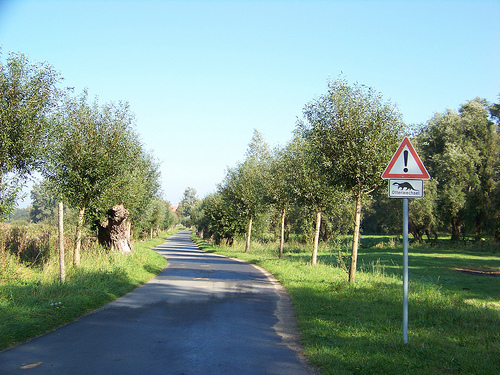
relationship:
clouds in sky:
[173, 72, 219, 123] [18, 7, 498, 108]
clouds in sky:
[163, 141, 234, 177] [3, 1, 495, 49]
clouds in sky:
[119, 57, 277, 180] [0, 2, 498, 208]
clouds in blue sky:
[135, 70, 255, 191] [164, 32, 240, 98]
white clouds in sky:
[116, 50, 184, 100] [0, 0, 500, 203]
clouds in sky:
[104, 39, 251, 179] [0, 2, 498, 208]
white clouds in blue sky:
[172, 140, 225, 182] [128, 15, 478, 63]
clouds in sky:
[110, 53, 257, 178] [13, 6, 496, 79]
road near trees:
[145, 207, 269, 365] [207, 106, 386, 266]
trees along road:
[203, 169, 368, 288] [38, 222, 311, 367]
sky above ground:
[126, 37, 290, 155] [22, 210, 467, 373]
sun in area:
[42, 13, 322, 149] [7, 185, 497, 372]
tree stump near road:
[93, 204, 132, 256] [0, 228, 319, 373]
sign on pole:
[366, 134, 463, 229] [370, 139, 451, 349]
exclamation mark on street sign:
[403, 148, 411, 174] [378, 135, 433, 180]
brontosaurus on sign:
[392, 175, 419, 193] [383, 178, 431, 200]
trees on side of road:
[187, 68, 412, 284] [35, 208, 300, 373]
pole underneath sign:
[399, 194, 411, 346] [374, 177, 426, 202]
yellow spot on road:
[21, 360, 41, 367] [0, 228, 319, 373]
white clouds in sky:
[147, 93, 225, 178] [0, 2, 498, 208]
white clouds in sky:
[172, 140, 225, 182] [0, 2, 498, 208]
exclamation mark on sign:
[403, 148, 411, 174] [380, 126, 442, 183]